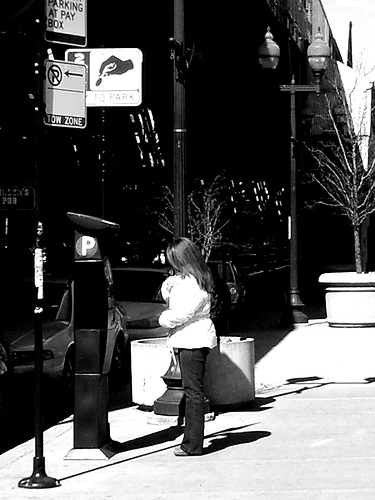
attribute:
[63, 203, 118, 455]
machine — metal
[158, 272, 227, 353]
coat — white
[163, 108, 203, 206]
pole — metal, black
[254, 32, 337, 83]
lights — black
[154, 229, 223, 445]
woman — standing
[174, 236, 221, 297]
hair — long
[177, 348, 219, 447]
pants — black